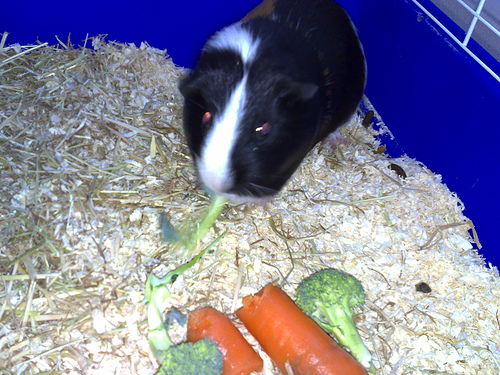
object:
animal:
[177, 0, 369, 204]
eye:
[255, 122, 271, 135]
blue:
[394, 64, 500, 154]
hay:
[0, 32, 201, 374]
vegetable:
[145, 193, 373, 375]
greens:
[158, 186, 231, 251]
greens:
[294, 267, 371, 369]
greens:
[135, 231, 230, 375]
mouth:
[208, 193, 245, 205]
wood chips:
[0, 31, 499, 375]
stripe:
[194, 69, 248, 193]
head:
[173, 65, 329, 205]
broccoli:
[294, 267, 371, 365]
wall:
[1, 0, 231, 66]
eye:
[201, 111, 211, 124]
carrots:
[184, 280, 370, 375]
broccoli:
[144, 229, 232, 375]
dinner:
[143, 194, 372, 375]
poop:
[388, 163, 407, 179]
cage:
[0, 0, 500, 375]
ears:
[178, 69, 319, 100]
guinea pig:
[175, 0, 370, 207]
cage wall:
[355, 0, 500, 285]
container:
[368, 10, 483, 224]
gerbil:
[175, 0, 366, 204]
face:
[190, 83, 280, 206]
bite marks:
[243, 293, 266, 309]